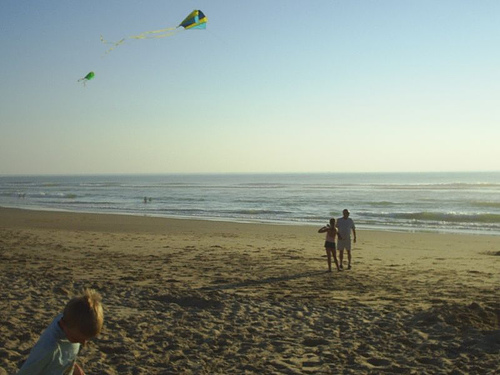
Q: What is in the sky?
A: Two kites.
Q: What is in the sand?
A: Foot prints.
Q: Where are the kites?
A: In the sky.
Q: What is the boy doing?
A: Playing on the beach.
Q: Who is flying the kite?
A: A man and woman.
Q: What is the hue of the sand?
A: Light brown.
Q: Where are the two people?
A: Next to the ocean.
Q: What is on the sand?
A: Shadow of the people.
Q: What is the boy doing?
A: Playing in the sand.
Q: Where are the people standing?
A: Beach.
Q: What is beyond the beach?
A: Water.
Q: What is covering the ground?
A: Sand.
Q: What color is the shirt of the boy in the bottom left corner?
A: White.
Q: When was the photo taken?
A: Daytime.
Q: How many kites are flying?
A: Two.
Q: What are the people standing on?
A: Sand.